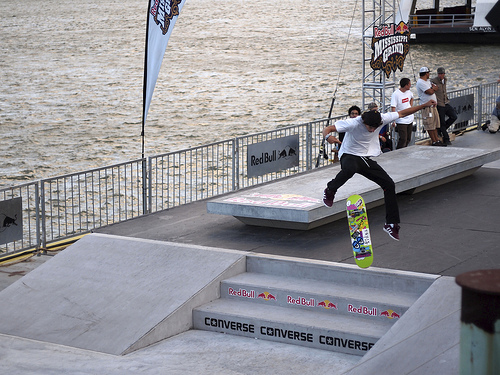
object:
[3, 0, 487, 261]
water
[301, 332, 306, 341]
black letter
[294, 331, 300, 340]
black letter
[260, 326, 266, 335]
black letter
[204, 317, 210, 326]
black letter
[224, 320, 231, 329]
black letter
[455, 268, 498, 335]
top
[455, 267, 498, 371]
pole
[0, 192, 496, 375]
skate park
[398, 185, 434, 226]
ground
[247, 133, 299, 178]
banner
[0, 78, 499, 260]
fence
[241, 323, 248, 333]
letter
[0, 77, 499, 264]
metal fencing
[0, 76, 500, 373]
pier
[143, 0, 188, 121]
flag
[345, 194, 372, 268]
skateboard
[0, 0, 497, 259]
river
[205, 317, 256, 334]
converse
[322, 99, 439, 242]
boy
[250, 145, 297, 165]
red bull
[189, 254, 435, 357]
stairs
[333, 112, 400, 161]
shirt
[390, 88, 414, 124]
shirt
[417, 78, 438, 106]
shirt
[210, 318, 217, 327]
letter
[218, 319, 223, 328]
letter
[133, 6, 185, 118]
fruit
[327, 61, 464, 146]
group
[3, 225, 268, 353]
ramp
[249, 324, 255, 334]
letter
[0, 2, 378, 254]
ocean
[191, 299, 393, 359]
step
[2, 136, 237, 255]
gates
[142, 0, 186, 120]
blue flag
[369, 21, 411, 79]
mississippi grand